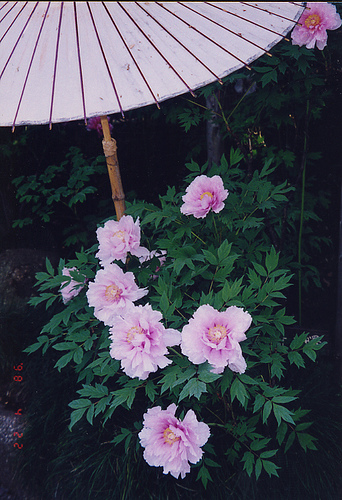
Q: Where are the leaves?
A: With flowers.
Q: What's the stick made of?
A: Wood.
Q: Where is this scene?
A: Garden.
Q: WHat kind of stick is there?
A: Bamboo.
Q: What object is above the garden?
A: Umbrella.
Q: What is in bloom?
A: Flowers.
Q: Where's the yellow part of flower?
A: In middle.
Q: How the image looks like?
A: Fresh.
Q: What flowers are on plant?
A: Pink.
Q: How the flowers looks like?
A: Beautiful.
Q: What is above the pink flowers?
A: Umbrella.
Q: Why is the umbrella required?
A: To cover the plants.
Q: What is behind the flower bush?
A: Foliage.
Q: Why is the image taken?
A: Remembrance.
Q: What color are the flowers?
A: Pink.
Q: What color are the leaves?
A: Green.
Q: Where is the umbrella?
A: Above flowers.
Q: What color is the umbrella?
A: Gray.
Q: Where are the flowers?
A: On leaves.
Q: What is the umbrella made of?
A: Wood.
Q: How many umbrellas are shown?
A: One.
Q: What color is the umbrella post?
A: Brown.